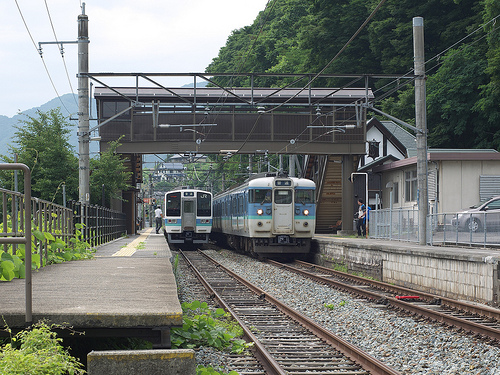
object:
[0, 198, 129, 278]
fence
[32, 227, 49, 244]
plants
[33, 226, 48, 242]
broad leaves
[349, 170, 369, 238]
post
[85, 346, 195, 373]
cement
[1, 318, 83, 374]
plant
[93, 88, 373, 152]
bridge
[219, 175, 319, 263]
train cars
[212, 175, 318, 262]
train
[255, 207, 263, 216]
headlights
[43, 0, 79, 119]
wires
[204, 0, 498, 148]
foliage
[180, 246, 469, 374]
train tracks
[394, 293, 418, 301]
item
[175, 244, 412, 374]
train track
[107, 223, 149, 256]
stripe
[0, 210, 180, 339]
sidewalk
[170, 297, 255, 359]
shrub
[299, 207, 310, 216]
lights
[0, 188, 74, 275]
rails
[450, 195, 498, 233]
car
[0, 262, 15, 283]
leaves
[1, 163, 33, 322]
bars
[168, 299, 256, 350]
plant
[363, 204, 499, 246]
fence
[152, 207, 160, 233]
person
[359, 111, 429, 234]
building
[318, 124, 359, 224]
stairway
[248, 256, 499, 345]
railroad tracks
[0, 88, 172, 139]
mountains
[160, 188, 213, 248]
train